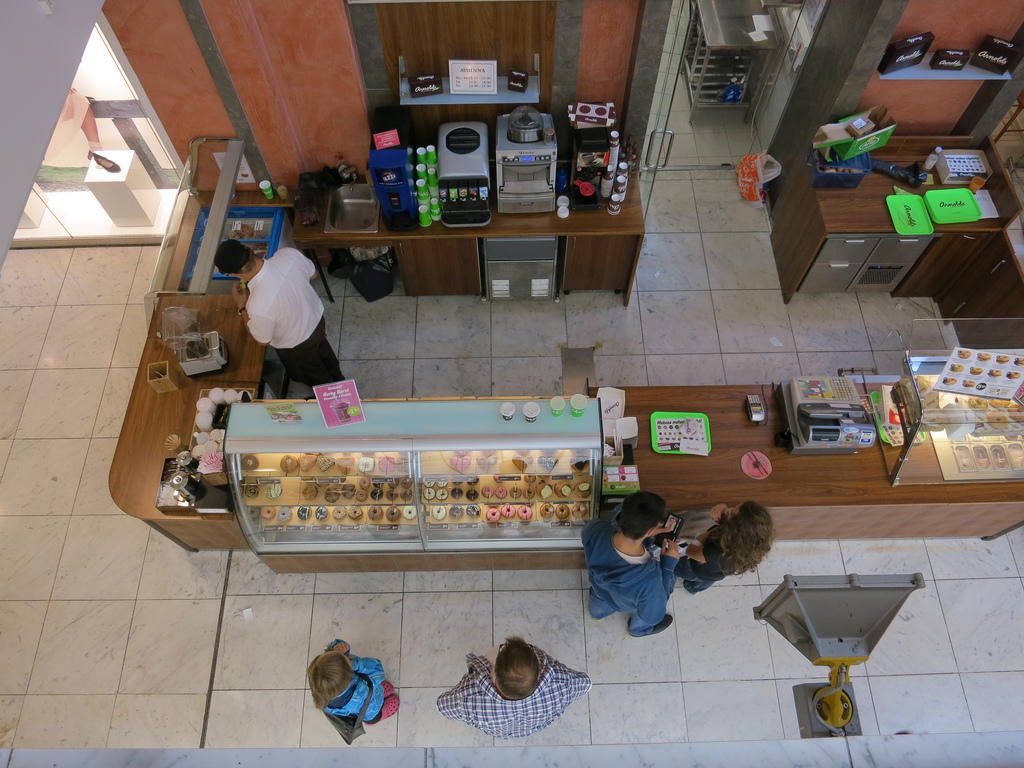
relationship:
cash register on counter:
[771, 366, 886, 460] [596, 374, 1021, 543]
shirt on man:
[220, 238, 335, 364] [210, 237, 348, 394]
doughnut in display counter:
[393, 498, 424, 527] [216, 383, 606, 585]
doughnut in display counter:
[475, 493, 508, 526] [216, 383, 606, 585]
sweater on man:
[578, 518, 680, 626] [579, 489, 678, 646]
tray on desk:
[879, 184, 938, 249] [769, 135, 1020, 304]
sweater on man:
[559, 508, 691, 640] [580, 492, 681, 640]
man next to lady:
[580, 492, 681, 640] [672, 497, 771, 596]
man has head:
[435, 644, 587, 737] [482, 625, 552, 706]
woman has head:
[307, 636, 409, 742] [296, 647, 363, 708]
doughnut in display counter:
[402, 505, 416, 520] [224, 393, 605, 574]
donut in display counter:
[508, 495, 541, 534] [224, 393, 605, 574]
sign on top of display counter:
[303, 364, 384, 434] [224, 393, 605, 574]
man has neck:
[572, 472, 698, 650] [580, 520, 667, 569]